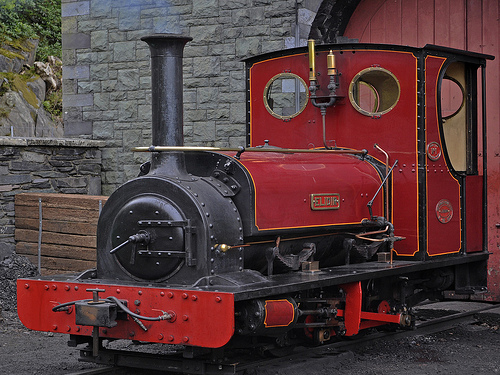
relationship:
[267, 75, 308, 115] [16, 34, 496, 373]
window on train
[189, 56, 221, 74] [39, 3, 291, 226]
brick on wall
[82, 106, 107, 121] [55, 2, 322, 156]
brick on wall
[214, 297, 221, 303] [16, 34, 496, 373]
bolt on train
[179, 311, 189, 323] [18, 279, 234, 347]
bolt on front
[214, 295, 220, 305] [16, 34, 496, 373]
bolt on train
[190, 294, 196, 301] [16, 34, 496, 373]
bolt on train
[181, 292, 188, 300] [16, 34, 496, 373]
bolt on train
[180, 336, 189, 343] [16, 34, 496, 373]
bolt on train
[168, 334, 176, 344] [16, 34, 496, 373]
bolt on train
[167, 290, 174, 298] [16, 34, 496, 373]
bolt on train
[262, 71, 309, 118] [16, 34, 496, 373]
window on train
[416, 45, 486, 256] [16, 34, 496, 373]
door on train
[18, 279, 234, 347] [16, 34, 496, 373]
front on train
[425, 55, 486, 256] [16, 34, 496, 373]
door on train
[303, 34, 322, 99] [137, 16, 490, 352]
whistle on train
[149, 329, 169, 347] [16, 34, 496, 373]
bolt in front of train